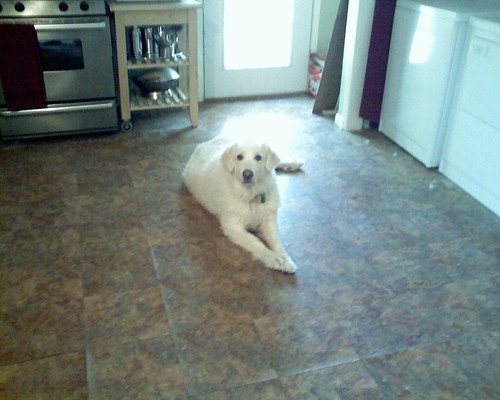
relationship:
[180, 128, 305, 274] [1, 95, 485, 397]
dog on floor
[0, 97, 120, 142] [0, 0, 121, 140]
drawer on oven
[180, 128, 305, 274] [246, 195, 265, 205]
dog wearing collar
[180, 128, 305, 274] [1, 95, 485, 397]
dog laying on floor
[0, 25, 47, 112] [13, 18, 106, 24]
maroon towel on door handle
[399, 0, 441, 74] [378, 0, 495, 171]
reflection on appliance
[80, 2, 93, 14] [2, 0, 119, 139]
knob on appliance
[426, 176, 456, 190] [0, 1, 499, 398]
paper on floor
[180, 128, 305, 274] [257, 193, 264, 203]
dog wearing collar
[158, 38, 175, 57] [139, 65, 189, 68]
kitchenware sitting on shelves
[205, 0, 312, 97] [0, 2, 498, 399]
door going to kitchen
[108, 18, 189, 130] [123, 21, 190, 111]
cart holding kitchenwares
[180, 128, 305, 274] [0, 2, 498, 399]
dog waiting in kitchen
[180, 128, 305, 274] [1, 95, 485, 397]
dog lying on floor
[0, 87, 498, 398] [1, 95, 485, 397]
tile on floor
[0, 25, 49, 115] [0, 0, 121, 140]
maroon towel hanging on oven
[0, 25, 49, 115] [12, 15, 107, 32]
maroon towel hanging on door handle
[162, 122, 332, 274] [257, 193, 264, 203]
dog wearing collar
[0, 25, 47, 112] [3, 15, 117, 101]
maroon towel hanging on oven door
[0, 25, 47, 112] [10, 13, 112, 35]
maroon towel hanging on handle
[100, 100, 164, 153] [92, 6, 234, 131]
wheel on cart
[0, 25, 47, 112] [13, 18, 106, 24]
maroon towel hanging on door handle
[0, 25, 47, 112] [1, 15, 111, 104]
maroon towel hanging on door